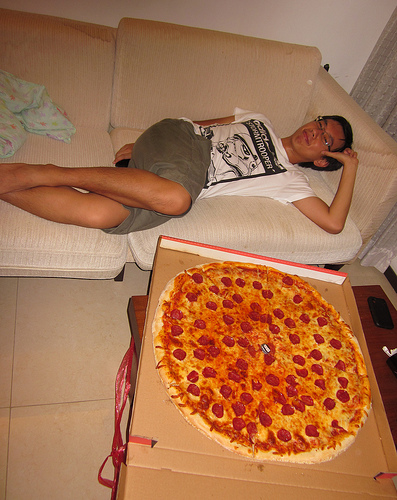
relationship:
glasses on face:
[312, 115, 341, 152] [293, 105, 394, 186]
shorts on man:
[137, 113, 245, 229] [40, 93, 392, 238]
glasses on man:
[312, 115, 341, 152] [40, 93, 392, 238]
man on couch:
[40, 93, 392, 238] [77, 40, 310, 126]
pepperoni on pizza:
[198, 340, 244, 376] [189, 268, 374, 437]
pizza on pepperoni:
[189, 268, 374, 437] [198, 340, 244, 376]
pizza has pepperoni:
[189, 268, 374, 437] [198, 340, 244, 376]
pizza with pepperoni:
[189, 268, 374, 437] [198, 340, 244, 376]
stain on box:
[247, 448, 280, 484] [144, 401, 205, 447]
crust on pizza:
[155, 272, 194, 347] [189, 268, 374, 437]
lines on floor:
[23, 368, 102, 427] [21, 321, 97, 491]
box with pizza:
[144, 401, 205, 447] [189, 268, 374, 437]